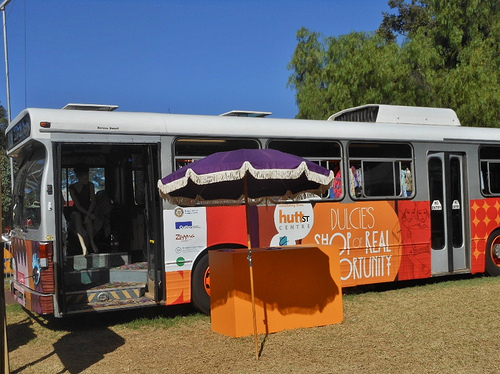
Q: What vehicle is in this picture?
A: A bus.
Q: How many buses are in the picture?
A: One.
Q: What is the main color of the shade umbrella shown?
A: Purple.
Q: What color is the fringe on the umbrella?
A: White.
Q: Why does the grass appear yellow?
A: It is dry.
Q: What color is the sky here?
A: Blue.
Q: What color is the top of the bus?
A: White.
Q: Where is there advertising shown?
A: On the side of the bus.